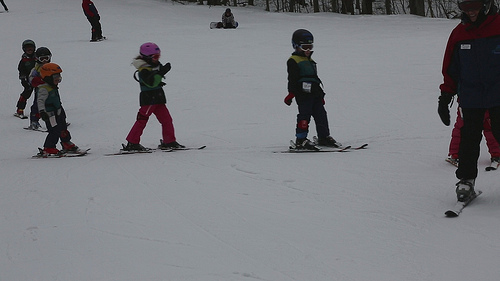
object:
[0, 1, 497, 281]
ground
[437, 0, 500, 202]
adult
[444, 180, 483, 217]
skis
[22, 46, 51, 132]
kids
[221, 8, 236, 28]
person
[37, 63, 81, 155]
kids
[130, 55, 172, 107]
coat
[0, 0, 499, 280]
snow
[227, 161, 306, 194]
tracks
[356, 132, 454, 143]
tracks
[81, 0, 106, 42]
person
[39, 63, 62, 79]
helmet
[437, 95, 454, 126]
glove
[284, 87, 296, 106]
glove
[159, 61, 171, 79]
glove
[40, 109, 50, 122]
glove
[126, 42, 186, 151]
kid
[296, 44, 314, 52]
goggles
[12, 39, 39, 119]
kids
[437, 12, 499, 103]
coat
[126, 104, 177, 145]
pants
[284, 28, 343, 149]
kids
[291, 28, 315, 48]
helmet